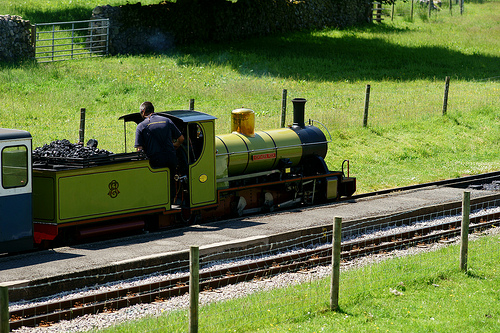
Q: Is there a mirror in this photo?
A: No, there are no mirrors.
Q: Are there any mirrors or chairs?
A: No, there are no mirrors or chairs.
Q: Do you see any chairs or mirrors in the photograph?
A: No, there are no mirrors or chairs.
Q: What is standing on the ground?
A: The wall is standing on the ground.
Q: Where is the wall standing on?
A: The wall is standing on the ground.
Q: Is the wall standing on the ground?
A: Yes, the wall is standing on the ground.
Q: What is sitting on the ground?
A: The wall is sitting on the ground.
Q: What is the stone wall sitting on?
A: The wall is sitting on the ground.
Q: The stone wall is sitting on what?
A: The wall is sitting on the ground.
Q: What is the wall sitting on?
A: The wall is sitting on the ground.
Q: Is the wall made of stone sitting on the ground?
A: Yes, the wall is sitting on the ground.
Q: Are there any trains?
A: Yes, there is a train.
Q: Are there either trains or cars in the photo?
A: Yes, there is a train.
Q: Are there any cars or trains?
A: Yes, there is a train.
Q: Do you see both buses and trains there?
A: No, there is a train but no buses.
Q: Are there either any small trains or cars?
A: Yes, there is a small train.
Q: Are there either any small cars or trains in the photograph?
A: Yes, there is a small train.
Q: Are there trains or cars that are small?
A: Yes, the train is small.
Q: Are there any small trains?
A: Yes, there is a small train.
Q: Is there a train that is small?
A: Yes, there is a train that is small.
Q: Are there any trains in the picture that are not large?
A: Yes, there is a small train.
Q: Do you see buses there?
A: No, there are no buses.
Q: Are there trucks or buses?
A: No, there are no buses or trucks.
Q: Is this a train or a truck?
A: This is a train.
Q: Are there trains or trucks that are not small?
A: No, there is a train but it is small.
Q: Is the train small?
A: Yes, the train is small.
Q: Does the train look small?
A: Yes, the train is small.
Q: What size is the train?
A: The train is small.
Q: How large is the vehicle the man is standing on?
A: The train is small.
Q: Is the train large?
A: No, the train is small.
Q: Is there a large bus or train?
A: No, there is a train but it is small.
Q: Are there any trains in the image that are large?
A: No, there is a train but it is small.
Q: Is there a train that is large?
A: No, there is a train but it is small.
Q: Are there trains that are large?
A: No, there is a train but it is small.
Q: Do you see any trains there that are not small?
A: No, there is a train but it is small.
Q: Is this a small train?
A: Yes, this is a small train.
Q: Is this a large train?
A: No, this is a small train.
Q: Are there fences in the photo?
A: Yes, there is a fence.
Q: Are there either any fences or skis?
A: Yes, there is a fence.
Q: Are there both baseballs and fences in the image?
A: No, there is a fence but no baseballs.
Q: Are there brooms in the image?
A: No, there are no brooms.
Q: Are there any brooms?
A: No, there are no brooms.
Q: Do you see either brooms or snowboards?
A: No, there are no brooms or snowboards.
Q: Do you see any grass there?
A: Yes, there is grass.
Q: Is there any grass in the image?
A: Yes, there is grass.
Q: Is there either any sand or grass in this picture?
A: Yes, there is grass.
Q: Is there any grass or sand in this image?
A: Yes, there is grass.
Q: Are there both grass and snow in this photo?
A: No, there is grass but no snow.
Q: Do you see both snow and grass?
A: No, there is grass but no snow.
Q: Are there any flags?
A: No, there are no flags.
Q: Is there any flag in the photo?
A: No, there are no flags.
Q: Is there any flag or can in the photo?
A: No, there are no flags or cans.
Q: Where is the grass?
A: The grass is on the ground.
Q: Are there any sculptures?
A: No, there are no sculptures.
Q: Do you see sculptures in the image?
A: No, there are no sculptures.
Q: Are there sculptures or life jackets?
A: No, there are no sculptures or life jackets.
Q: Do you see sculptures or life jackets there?
A: No, there are no sculptures or life jackets.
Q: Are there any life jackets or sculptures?
A: No, there are no sculptures or life jackets.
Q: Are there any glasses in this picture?
A: No, there are no glasses.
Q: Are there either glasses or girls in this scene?
A: No, there are no glasses or girls.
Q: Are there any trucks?
A: No, there are no trucks.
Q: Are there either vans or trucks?
A: No, there are no trucks or vans.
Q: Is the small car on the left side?
A: Yes, the car is on the left of the image.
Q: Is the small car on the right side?
A: No, the car is on the left of the image.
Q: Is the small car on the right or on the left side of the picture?
A: The car is on the left of the image.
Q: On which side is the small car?
A: The car is on the left of the image.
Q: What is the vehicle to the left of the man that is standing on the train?
A: The vehicle is a car.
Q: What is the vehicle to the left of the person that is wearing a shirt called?
A: The vehicle is a car.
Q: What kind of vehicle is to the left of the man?
A: The vehicle is a car.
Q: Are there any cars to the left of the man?
A: Yes, there is a car to the left of the man.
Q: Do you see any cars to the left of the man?
A: Yes, there is a car to the left of the man.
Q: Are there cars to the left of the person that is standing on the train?
A: Yes, there is a car to the left of the man.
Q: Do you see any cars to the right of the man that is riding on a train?
A: No, the car is to the left of the man.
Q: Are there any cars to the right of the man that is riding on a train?
A: No, the car is to the left of the man.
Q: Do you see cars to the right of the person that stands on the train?
A: No, the car is to the left of the man.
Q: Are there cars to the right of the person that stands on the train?
A: No, the car is to the left of the man.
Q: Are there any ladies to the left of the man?
A: No, there is a car to the left of the man.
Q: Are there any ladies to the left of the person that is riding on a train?
A: No, there is a car to the left of the man.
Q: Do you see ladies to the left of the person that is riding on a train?
A: No, there is a car to the left of the man.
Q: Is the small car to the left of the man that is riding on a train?
A: Yes, the car is to the left of the man.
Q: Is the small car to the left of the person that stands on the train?
A: Yes, the car is to the left of the man.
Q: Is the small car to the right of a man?
A: No, the car is to the left of a man.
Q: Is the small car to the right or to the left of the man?
A: The car is to the left of the man.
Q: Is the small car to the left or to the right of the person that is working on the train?
A: The car is to the left of the man.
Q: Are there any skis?
A: No, there are no skis.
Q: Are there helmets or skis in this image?
A: No, there are no skis or helmets.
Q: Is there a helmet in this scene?
A: No, there are no helmets.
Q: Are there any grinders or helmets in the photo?
A: No, there are no helmets or grinders.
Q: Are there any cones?
A: No, there are no cones.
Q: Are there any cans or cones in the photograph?
A: No, there are no cones or cans.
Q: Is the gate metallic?
A: Yes, the gate is metallic.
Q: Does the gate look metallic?
A: Yes, the gate is metallic.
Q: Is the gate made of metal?
A: Yes, the gate is made of metal.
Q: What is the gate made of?
A: The gate is made of metal.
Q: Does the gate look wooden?
A: No, the gate is metallic.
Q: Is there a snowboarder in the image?
A: No, there are no snowboarders.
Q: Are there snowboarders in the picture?
A: No, there are no snowboarders.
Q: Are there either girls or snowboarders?
A: No, there are no snowboarders or girls.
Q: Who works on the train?
A: The man works on the train.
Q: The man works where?
A: The man works on the train.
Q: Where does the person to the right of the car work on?
A: The man works on the train.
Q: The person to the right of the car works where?
A: The man works on the train.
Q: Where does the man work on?
A: The man works on the train.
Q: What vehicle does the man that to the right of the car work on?
A: The man works on the train.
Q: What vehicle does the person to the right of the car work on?
A: The man works on the train.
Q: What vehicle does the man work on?
A: The man works on the train.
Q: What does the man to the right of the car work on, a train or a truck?
A: The man works on a train.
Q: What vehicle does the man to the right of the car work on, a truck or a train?
A: The man works on a train.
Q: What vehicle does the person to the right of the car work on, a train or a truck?
A: The man works on a train.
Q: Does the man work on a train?
A: Yes, the man works on a train.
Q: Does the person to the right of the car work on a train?
A: Yes, the man works on a train.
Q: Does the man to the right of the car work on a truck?
A: No, the man works on a train.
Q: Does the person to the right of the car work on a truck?
A: No, the man works on a train.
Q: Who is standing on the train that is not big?
A: The man is standing on the train.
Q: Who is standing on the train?
A: The man is standing on the train.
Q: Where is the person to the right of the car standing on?
A: The man is standing on the train.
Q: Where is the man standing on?
A: The man is standing on the train.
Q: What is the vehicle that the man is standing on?
A: The vehicle is a train.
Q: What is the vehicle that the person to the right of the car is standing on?
A: The vehicle is a train.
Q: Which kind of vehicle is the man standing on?
A: The man is standing on the train.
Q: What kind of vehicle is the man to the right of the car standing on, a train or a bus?
A: The man is standing on a train.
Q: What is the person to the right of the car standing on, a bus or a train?
A: The man is standing on a train.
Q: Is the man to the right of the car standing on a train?
A: Yes, the man is standing on a train.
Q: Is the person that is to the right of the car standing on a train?
A: Yes, the man is standing on a train.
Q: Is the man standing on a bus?
A: No, the man is standing on a train.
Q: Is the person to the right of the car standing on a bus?
A: No, the man is standing on a train.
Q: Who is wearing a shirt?
A: The man is wearing a shirt.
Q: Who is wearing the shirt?
A: The man is wearing a shirt.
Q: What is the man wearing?
A: The man is wearing a shirt.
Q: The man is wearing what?
A: The man is wearing a shirt.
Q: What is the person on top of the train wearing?
A: The man is wearing a shirt.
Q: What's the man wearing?
A: The man is wearing a shirt.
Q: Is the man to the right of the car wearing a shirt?
A: Yes, the man is wearing a shirt.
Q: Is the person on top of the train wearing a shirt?
A: Yes, the man is wearing a shirt.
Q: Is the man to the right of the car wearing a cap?
A: No, the man is wearing a shirt.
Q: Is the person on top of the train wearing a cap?
A: No, the man is wearing a shirt.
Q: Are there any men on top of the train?
A: Yes, there is a man on top of the train.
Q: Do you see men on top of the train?
A: Yes, there is a man on top of the train.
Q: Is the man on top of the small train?
A: Yes, the man is on top of the train.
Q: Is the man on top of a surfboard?
A: No, the man is on top of the train.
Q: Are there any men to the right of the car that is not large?
A: Yes, there is a man to the right of the car.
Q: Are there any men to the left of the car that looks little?
A: No, the man is to the right of the car.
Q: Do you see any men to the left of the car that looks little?
A: No, the man is to the right of the car.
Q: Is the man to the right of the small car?
A: Yes, the man is to the right of the car.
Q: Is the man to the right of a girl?
A: No, the man is to the right of the car.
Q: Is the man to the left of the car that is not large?
A: No, the man is to the right of the car.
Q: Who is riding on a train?
A: The man is riding on a train.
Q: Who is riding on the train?
A: The man is riding on a train.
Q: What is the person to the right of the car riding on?
A: The man is riding on a train.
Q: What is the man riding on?
A: The man is riding on a train.